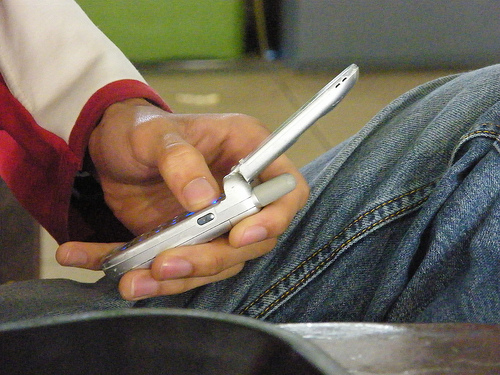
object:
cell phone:
[102, 63, 361, 283]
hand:
[55, 103, 312, 304]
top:
[236, 63, 358, 183]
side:
[100, 63, 360, 282]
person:
[0, 0, 500, 324]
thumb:
[152, 133, 220, 212]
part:
[47, 42, 104, 88]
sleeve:
[0, 0, 173, 245]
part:
[373, 112, 406, 144]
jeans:
[0, 63, 500, 330]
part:
[309, 11, 332, 33]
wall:
[281, 0, 500, 68]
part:
[221, 87, 238, 98]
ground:
[139, 60, 470, 171]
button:
[198, 213, 215, 225]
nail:
[182, 177, 217, 205]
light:
[118, 195, 225, 251]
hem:
[240, 132, 500, 320]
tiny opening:
[336, 77, 347, 87]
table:
[277, 321, 500, 375]